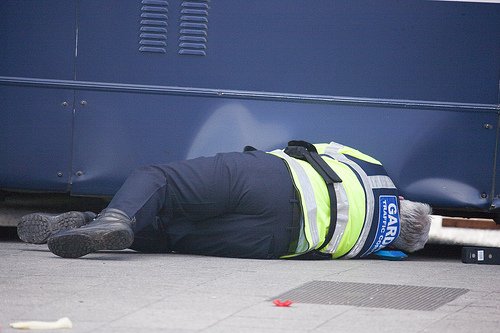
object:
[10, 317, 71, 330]
glove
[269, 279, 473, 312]
vent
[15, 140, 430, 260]
man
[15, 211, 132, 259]
shoe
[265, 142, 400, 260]
vest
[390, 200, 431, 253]
hair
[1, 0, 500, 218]
train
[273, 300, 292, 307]
trash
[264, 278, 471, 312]
water drain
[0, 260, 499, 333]
ground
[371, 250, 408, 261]
cushion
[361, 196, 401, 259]
word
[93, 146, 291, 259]
pant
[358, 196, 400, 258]
sign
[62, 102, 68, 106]
bolts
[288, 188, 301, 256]
belt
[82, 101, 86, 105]
screw